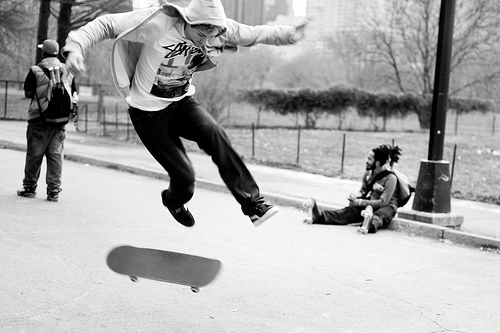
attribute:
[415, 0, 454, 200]
pole — black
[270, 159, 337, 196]
sidewalk — grey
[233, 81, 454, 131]
plants fence — growing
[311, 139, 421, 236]
man — sitting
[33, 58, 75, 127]
backpack — dark colored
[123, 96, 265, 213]
pants — dark colored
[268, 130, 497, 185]
grass — grey